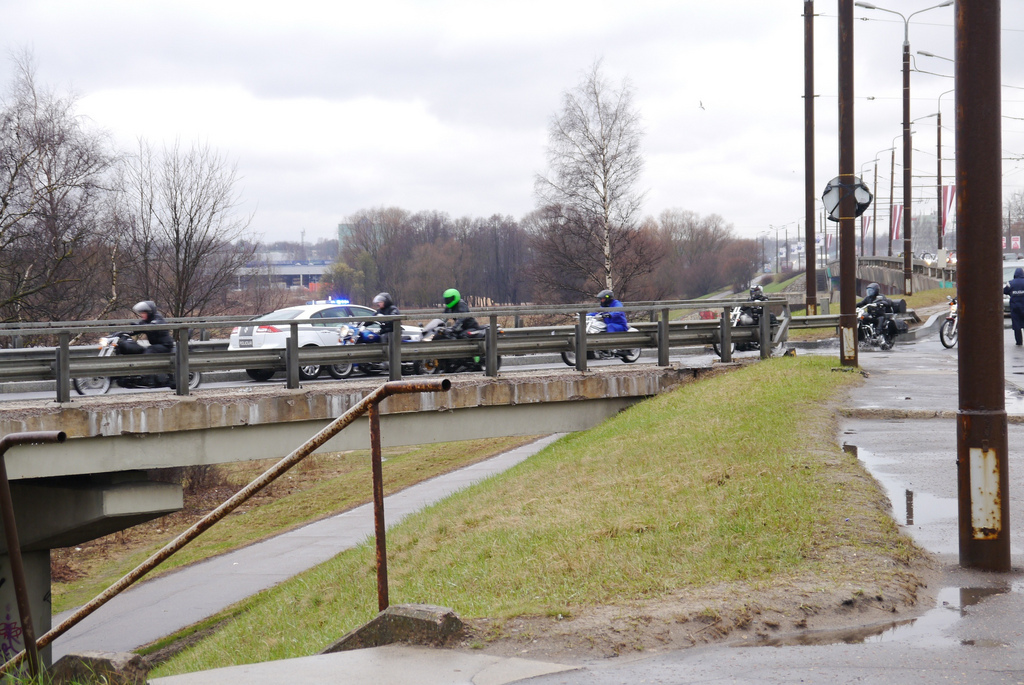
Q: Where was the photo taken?
A: At a bridge.